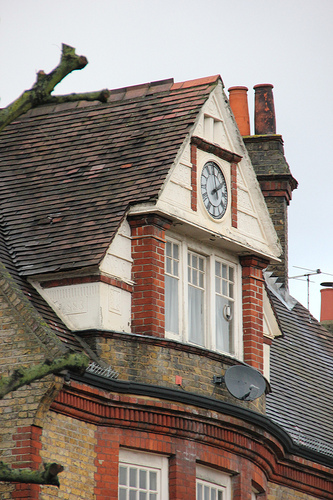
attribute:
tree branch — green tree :
[0, 42, 89, 130]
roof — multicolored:
[0, 74, 279, 282]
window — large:
[164, 235, 235, 356]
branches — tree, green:
[5, 41, 102, 121]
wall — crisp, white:
[73, 285, 120, 329]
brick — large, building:
[134, 258, 153, 269]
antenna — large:
[287, 261, 319, 308]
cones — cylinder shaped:
[220, 77, 297, 148]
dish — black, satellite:
[214, 363, 272, 400]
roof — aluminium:
[6, 45, 330, 280]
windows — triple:
[160, 231, 248, 357]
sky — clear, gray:
[0, 1, 331, 321]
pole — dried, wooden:
[2, 45, 114, 134]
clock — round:
[200, 157, 229, 219]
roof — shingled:
[14, 109, 220, 237]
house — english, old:
[14, 77, 321, 498]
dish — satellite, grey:
[217, 365, 278, 402]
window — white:
[120, 452, 166, 496]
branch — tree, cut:
[4, 36, 114, 161]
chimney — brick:
[252, 81, 278, 132]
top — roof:
[43, 78, 168, 194]